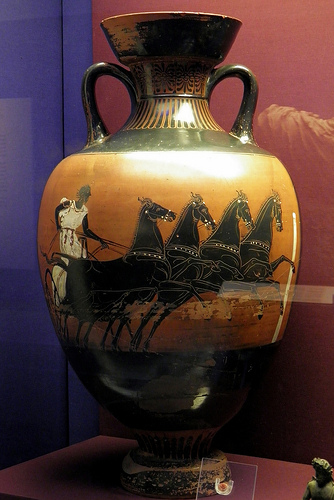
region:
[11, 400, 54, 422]
this is the wall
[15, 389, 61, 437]
the wall is clean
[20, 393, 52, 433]
the wall is purple in color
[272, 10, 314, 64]
the wall is brown in color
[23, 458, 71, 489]
this is a table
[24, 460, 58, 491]
the table is wooden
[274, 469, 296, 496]
the table is brown in color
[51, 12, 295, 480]
this is a vase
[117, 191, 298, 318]
drawings of some horses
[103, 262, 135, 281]
the horse is black in color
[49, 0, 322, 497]
This is a pot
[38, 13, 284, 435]
large urn on top of table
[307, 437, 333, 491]
greenish looking figure on right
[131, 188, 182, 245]
black horse picture on urn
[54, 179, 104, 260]
chariot driver on urn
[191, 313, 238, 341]
orangish brown color on urn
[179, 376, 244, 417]
light colored refection on urn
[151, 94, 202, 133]
brown and black colored stripes on urn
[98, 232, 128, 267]
reins for horses on urn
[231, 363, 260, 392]
black patch of color on urn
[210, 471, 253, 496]
yellow and white area on right of urn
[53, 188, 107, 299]
image of a man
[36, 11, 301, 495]
a greek style vase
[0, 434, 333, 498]
the table is square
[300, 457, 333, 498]
the figure is green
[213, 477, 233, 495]
piece of junk on bottom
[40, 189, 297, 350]
four black horses in a line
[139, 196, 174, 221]
head of a horse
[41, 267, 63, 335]
wheel of a chariot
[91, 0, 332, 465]
the wall is pink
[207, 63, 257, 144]
handle of the vase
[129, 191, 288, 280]
four horses on the vase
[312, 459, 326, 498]
green statue on the table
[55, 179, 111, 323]
picture of man in a chariot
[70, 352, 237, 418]
bottom of vase is black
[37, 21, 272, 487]
vase is black and gold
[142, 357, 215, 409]
worn marking on front of vase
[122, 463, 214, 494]
base of item is black and white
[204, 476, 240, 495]
small white item in case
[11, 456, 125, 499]
top of table is brown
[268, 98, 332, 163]
picture on the wall behind the vase